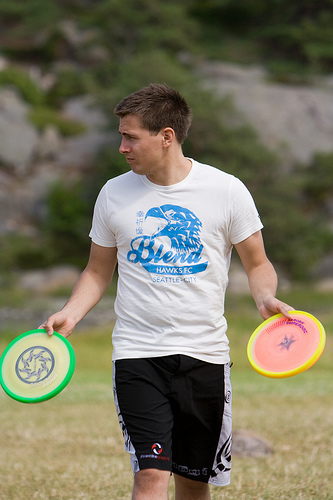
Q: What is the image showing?
A: It is showing a park.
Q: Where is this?
A: This is at the park.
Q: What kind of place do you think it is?
A: It is a park.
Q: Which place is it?
A: It is a park.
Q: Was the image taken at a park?
A: Yes, it was taken in a park.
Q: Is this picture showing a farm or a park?
A: It is showing a park.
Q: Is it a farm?
A: No, it is a park.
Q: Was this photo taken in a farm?
A: No, the picture was taken in a park.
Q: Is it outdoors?
A: Yes, it is outdoors.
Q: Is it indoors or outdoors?
A: It is outdoors.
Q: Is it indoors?
A: No, it is outdoors.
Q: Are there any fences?
A: No, there are no fences.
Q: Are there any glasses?
A: No, there are no glasses.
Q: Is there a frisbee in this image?
A: Yes, there is a frisbee.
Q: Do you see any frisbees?
A: Yes, there is a frisbee.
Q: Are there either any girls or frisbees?
A: Yes, there is a frisbee.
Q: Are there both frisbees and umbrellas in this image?
A: No, there is a frisbee but no umbrellas.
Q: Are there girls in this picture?
A: No, there are no girls.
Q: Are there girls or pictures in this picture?
A: No, there are no girls or pictures.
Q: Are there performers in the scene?
A: No, there are no performers.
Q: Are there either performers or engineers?
A: No, there are no performers or engineers.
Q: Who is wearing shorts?
A: The man is wearing shorts.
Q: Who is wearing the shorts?
A: The man is wearing shorts.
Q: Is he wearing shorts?
A: Yes, the man is wearing shorts.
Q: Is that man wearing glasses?
A: No, the man is wearing shorts.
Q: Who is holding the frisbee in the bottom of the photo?
A: The man is holding the frisbee.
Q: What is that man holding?
A: The man is holding the frisbee.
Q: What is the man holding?
A: The man is holding the frisbee.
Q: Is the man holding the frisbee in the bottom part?
A: Yes, the man is holding the frisbee.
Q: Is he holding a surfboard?
A: No, the man is holding the frisbee.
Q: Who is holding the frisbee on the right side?
A: The man is holding the frisbee.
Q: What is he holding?
A: The man is holding the frisbee.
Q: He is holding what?
A: The man is holding the frisbee.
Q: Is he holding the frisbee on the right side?
A: Yes, the man is holding the frisbee.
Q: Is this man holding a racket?
A: No, the man is holding the frisbee.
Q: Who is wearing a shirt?
A: The man is wearing a shirt.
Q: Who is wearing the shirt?
A: The man is wearing a shirt.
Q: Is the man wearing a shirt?
A: Yes, the man is wearing a shirt.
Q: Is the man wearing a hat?
A: No, the man is wearing a shirt.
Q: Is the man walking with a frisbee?
A: Yes, the man is walking with a frisbee.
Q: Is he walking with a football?
A: No, the man is walking with a frisbee.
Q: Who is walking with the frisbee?
A: The man is walking with the frisbee.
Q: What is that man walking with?
A: The man is walking with a frisbee.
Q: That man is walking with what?
A: The man is walking with a frisbee.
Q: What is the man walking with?
A: The man is walking with a frisbee.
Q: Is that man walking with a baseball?
A: No, the man is walking with a frisbee.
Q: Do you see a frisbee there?
A: Yes, there is a frisbee.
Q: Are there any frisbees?
A: Yes, there is a frisbee.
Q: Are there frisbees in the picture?
A: Yes, there is a frisbee.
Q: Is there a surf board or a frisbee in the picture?
A: Yes, there is a frisbee.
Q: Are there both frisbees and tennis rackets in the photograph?
A: No, there is a frisbee but no rackets.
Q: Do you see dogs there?
A: No, there are no dogs.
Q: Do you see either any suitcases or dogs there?
A: No, there are no dogs or suitcases.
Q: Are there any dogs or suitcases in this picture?
A: No, there are no dogs or suitcases.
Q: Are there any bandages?
A: No, there are no bandages.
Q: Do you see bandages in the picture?
A: No, there are no bandages.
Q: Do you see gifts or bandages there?
A: No, there are no bandages or gifts.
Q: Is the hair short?
A: Yes, the hair is short.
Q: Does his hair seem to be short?
A: Yes, the hair is short.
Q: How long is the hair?
A: The hair is short.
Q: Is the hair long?
A: No, the hair is short.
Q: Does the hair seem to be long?
A: No, the hair is short.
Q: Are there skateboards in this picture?
A: No, there are no skateboards.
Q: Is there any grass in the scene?
A: Yes, there is grass.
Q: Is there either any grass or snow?
A: Yes, there is grass.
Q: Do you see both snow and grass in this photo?
A: No, there is grass but no snow.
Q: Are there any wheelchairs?
A: No, there are no wheelchairs.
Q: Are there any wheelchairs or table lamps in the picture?
A: No, there are no wheelchairs or table lamps.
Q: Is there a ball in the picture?
A: No, there are no balls.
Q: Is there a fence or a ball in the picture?
A: No, there are no balls or fences.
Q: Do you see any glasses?
A: No, there are no glasses.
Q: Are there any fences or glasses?
A: No, there are no glasses or fences.